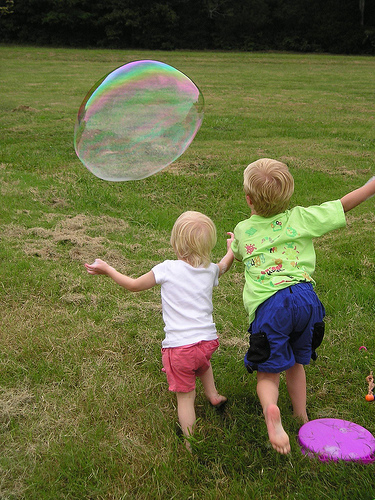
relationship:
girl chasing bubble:
[89, 214, 238, 456] [69, 61, 205, 183]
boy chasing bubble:
[231, 159, 374, 457] [69, 61, 205, 183]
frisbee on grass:
[300, 415, 374, 460] [3, 45, 374, 498]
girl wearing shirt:
[89, 214, 238, 456] [155, 258, 224, 353]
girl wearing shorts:
[89, 214, 238, 456] [166, 341, 222, 395]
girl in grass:
[89, 214, 238, 456] [3, 45, 374, 498]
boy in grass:
[231, 159, 374, 457] [3, 45, 374, 498]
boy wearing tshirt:
[231, 159, 374, 457] [231, 200, 347, 323]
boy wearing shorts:
[231, 159, 374, 457] [239, 280, 330, 378]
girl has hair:
[89, 214, 238, 456] [166, 209, 218, 270]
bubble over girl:
[69, 61, 205, 183] [89, 214, 238, 456]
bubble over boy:
[69, 61, 205, 183] [231, 159, 374, 457]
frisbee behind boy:
[300, 415, 374, 460] [231, 159, 374, 457]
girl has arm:
[89, 214, 238, 456] [216, 245, 238, 279]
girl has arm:
[89, 214, 238, 456] [108, 262, 163, 295]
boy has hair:
[231, 159, 374, 457] [242, 155, 296, 217]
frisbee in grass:
[298, 417, 375, 462] [3, 45, 374, 498]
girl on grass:
[89, 214, 238, 456] [3, 45, 374, 498]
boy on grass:
[231, 159, 374, 457] [3, 45, 374, 498]